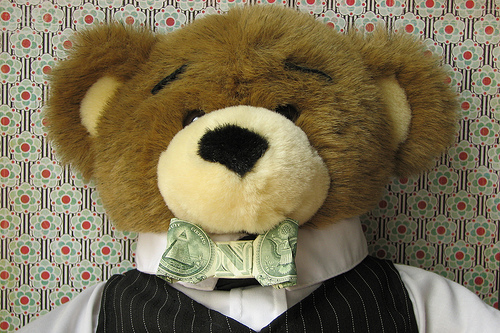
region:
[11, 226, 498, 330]
Bear is wearing a shirt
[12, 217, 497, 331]
Bear is wearing a white shirt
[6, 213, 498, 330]
Bear is wearing a dress shirt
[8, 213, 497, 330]
Bear is wearing a white dress shirt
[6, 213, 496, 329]
Teddy bear is wearing a shirt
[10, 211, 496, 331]
Teddy bear is wearing a dress shirt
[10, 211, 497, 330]
Teddy bear is wearing a white dress shirt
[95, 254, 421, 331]
Bear is wearing a vest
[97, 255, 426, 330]
Teddy bear is wearing a vest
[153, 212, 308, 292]
Bear is wearing a bow tie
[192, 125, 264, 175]
The teddy bears nose is black.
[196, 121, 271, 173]
The teddy bears nose is large.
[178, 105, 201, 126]
The teddy bears eye is small.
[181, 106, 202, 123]
The teddy bears eye is brown.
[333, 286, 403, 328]
The teddy bears vest is striped.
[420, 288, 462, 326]
The teddy bears shirt is white.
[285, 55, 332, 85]
The teddy bears eyebrow is thin.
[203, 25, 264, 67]
The teddy bears fur is brown.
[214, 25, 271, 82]
The teddy bears fur is fluffy.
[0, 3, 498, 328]
upper chest and head of teddy bear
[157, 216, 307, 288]
money design bow tie of bear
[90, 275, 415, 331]
striped vest of teddy bear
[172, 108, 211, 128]
eye of teddy bear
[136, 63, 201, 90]
eyebrow of teddy bear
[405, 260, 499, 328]
white undershirt of teddy bear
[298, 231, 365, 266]
collar on bear's outfit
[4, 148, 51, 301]
backdrop that bear is photographed on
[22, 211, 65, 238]
floral pattern on backdrop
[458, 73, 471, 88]
striped pattern on backdrop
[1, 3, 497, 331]
brown stuffed bear up against a wall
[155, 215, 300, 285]
bow tie made out of a dollar bill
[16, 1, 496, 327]
stuffed bear in white shirt and pinstripe vest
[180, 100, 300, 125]
plastic eyes of the bear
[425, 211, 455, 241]
green, red and white flower pattern on wall paper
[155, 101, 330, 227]
crea colored bears snoout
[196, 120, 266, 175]
black nose on the bear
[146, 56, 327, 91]
black eyebrows on the bear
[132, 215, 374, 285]
collar of the white shirt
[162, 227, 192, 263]
pyramid on the dollar bill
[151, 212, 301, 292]
The tie is made of money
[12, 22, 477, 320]
The teddy bear is dressed up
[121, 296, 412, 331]
The teddy bear has on a vest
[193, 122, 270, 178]
The nose on the teddy bear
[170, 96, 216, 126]
The eye of the teddy bear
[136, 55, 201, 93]
The eye brow of the teddy bear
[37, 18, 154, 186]
The ear of the teddy bear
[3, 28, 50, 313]
The wall paper is a floral design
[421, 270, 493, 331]
The teddy bear is wearing a white shirt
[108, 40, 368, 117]
The teddy bear is the color brown